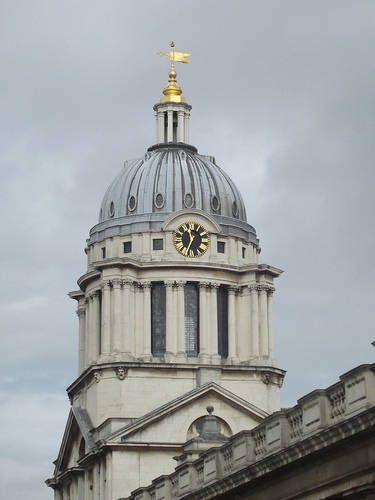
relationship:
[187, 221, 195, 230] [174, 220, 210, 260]
numeral on clock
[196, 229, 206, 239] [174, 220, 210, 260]
numeral on clock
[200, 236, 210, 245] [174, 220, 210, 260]
numeral on clock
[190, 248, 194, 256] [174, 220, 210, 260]
numbers on clock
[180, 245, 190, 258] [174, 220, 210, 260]
numeral on clock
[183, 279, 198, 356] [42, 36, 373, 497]
window on building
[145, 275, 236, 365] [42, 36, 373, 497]
windows on building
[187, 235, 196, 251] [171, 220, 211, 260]
hand on clock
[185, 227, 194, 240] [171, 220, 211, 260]
hand on clock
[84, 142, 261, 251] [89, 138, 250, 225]
dome has dome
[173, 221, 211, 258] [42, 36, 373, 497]
clock has building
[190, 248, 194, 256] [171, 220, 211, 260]
numbers on clock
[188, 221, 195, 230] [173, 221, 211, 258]
numeral on clock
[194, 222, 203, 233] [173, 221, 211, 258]
roman numeral on clock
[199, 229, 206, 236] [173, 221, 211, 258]
numeral on clock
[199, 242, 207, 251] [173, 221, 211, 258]
roman numeral on clock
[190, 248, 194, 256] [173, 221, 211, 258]
numbers on clock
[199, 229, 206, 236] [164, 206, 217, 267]
numeral on clock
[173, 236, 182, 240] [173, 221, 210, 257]
roman numeral on clock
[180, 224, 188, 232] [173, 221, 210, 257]
roman numeral on clock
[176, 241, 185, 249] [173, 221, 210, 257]
numbers on clock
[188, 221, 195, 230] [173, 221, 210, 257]
numeral on clock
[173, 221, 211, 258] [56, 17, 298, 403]
clock on tower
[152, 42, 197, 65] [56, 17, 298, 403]
flag on tower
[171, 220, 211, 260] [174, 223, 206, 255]
clock has roman numerals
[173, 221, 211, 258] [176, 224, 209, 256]
clock has background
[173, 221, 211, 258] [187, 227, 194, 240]
clock has hand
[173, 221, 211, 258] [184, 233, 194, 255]
clock has hand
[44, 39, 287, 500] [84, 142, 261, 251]
tower has dome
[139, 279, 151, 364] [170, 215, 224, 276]
column under clock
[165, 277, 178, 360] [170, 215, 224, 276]
column under clock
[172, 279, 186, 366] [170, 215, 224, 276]
column under clock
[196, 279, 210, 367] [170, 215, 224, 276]
column under clock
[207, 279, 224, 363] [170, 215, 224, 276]
column under clock